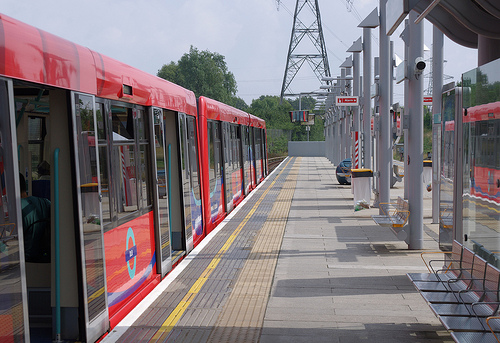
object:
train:
[0, 14, 267, 343]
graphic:
[123, 226, 137, 279]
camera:
[410, 57, 426, 78]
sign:
[335, 95, 357, 107]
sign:
[420, 95, 431, 103]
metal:
[396, 9, 424, 251]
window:
[109, 140, 139, 223]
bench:
[404, 240, 499, 342]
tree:
[155, 45, 249, 113]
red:
[106, 245, 121, 289]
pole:
[48, 145, 62, 341]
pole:
[373, 0, 392, 214]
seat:
[411, 246, 474, 292]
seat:
[426, 260, 499, 317]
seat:
[432, 301, 499, 332]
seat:
[443, 315, 499, 342]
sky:
[0, 0, 478, 114]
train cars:
[198, 93, 250, 237]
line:
[148, 156, 298, 342]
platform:
[101, 0, 499, 342]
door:
[10, 80, 83, 342]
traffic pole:
[352, 130, 360, 172]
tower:
[278, 0, 336, 100]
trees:
[249, 94, 295, 157]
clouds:
[0, 0, 479, 110]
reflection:
[455, 100, 499, 232]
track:
[266, 155, 286, 174]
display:
[435, 83, 464, 257]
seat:
[405, 239, 463, 282]